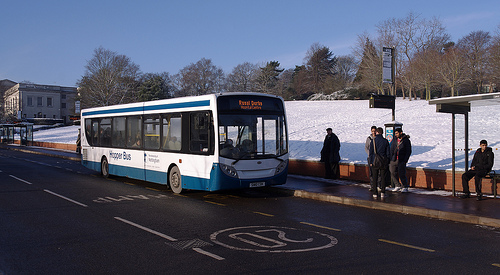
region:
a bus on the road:
[107, 60, 374, 273]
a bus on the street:
[83, 57, 295, 218]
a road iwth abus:
[157, 70, 304, 259]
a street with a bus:
[111, 84, 353, 271]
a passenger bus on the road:
[60, 65, 438, 271]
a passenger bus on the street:
[64, 36, 426, 273]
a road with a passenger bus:
[71, 41, 393, 273]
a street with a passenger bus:
[59, 72, 354, 239]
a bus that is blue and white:
[89, 61, 342, 258]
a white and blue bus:
[79, 72, 314, 234]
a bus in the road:
[31, 51, 408, 222]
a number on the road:
[210, 195, 325, 273]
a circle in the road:
[207, 210, 341, 273]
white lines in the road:
[124, 203, 196, 245]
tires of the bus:
[42, 120, 231, 212]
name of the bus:
[83, 134, 158, 172]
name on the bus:
[83, 135, 155, 174]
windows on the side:
[78, 95, 234, 160]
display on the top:
[223, 88, 283, 125]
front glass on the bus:
[219, 112, 308, 174]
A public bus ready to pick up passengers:
[71, 82, 306, 209]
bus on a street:
[68, 95, 294, 196]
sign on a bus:
[226, 90, 272, 118]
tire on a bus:
[148, 158, 196, 198]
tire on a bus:
[82, 153, 120, 179]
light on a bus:
[220, 155, 250, 195]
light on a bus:
[267, 150, 297, 175]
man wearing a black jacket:
[465, 133, 492, 194]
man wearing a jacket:
[387, 123, 417, 198]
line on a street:
[111, 208, 177, 249]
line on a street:
[37, 177, 84, 213]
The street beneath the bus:
[2, 144, 499, 274]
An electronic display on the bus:
[237, 98, 267, 112]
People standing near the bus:
[322, 126, 493, 201]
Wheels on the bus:
[100, 157, 181, 192]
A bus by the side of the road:
[79, 92, 288, 193]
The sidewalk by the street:
[0, 140, 497, 225]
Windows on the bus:
[84, 110, 214, 152]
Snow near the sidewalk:
[33, 94, 498, 169]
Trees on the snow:
[79, 14, 496, 109]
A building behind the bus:
[5, 83, 78, 125]